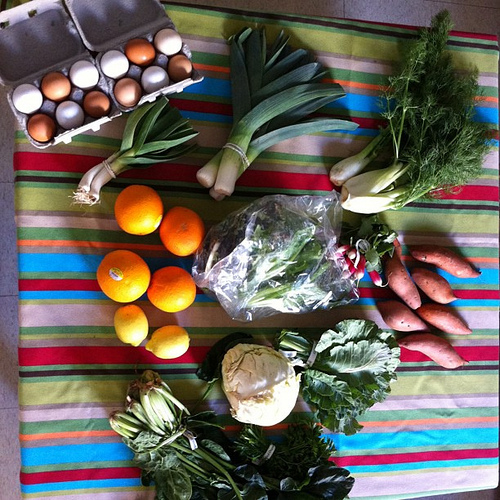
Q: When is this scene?
A: Daytime.